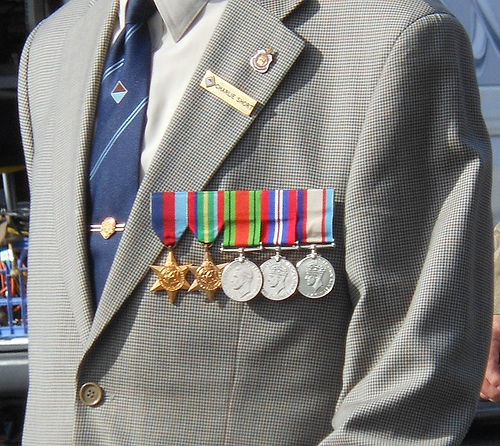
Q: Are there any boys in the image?
A: No, there are no boys.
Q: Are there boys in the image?
A: No, there are no boys.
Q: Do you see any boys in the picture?
A: No, there are no boys.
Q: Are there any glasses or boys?
A: No, there are no boys or glasses.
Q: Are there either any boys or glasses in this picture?
A: No, there are no boys or glasses.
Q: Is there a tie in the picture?
A: Yes, there is a tie.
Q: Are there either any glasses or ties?
A: Yes, there is a tie.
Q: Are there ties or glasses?
A: Yes, there is a tie.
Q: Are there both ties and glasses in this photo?
A: No, there is a tie but no glasses.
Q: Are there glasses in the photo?
A: No, there are no glasses.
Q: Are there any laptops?
A: No, there are no laptops.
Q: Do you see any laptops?
A: No, there are no laptops.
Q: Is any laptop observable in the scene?
A: No, there are no laptops.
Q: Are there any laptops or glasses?
A: No, there are no laptops or glasses.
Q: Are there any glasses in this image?
A: No, there are no glasses.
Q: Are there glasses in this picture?
A: No, there are no glasses.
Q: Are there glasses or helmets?
A: No, there are no glasses or helmets.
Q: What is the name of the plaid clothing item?
A: The clothing item is a jacket.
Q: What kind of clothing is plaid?
A: The clothing is a jacket.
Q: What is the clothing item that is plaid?
A: The clothing item is a jacket.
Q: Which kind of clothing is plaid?
A: The clothing is a jacket.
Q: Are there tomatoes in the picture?
A: Yes, there is a tomato.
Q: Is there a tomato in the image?
A: Yes, there is a tomato.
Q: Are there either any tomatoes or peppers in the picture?
A: Yes, there is a tomato.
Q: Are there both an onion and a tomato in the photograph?
A: No, there is a tomato but no onions.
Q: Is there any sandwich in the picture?
A: No, there are no sandwiches.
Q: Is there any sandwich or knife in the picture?
A: No, there are no sandwiches or knives.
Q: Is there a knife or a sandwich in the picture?
A: No, there are no sandwiches or knives.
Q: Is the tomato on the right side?
A: Yes, the tomato is on the right of the image.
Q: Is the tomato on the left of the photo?
A: No, the tomato is on the right of the image.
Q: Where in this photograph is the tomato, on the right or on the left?
A: The tomato is on the right of the image.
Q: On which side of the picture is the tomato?
A: The tomato is on the right of the image.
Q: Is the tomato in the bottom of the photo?
A: Yes, the tomato is in the bottom of the image.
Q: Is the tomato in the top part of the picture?
A: No, the tomato is in the bottom of the image.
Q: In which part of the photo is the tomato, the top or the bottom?
A: The tomato is in the bottom of the image.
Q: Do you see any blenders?
A: Yes, there is a blender.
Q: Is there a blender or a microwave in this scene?
A: Yes, there is a blender.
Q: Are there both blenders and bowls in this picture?
A: No, there is a blender but no bowls.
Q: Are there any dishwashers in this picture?
A: No, there are no dishwashers.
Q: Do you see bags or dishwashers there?
A: No, there are no dishwashers or bags.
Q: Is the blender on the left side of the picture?
A: Yes, the blender is on the left of the image.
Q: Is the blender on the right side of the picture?
A: No, the blender is on the left of the image.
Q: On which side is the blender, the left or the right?
A: The blender is on the left of the image.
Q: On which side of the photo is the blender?
A: The blender is on the left of the image.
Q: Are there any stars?
A: Yes, there is a star.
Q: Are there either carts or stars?
A: Yes, there is a star.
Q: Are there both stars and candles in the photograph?
A: No, there is a star but no candles.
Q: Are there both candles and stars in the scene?
A: No, there is a star but no candles.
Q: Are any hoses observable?
A: No, there are no hoses.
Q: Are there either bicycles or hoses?
A: No, there are no hoses or bicycles.